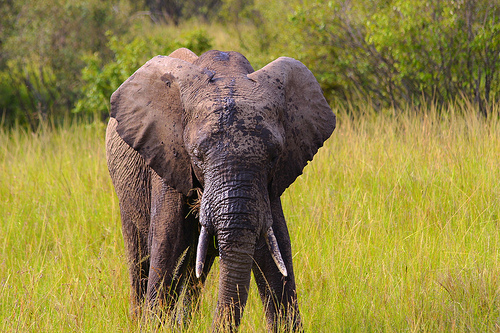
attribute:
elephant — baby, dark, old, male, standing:
[90, 32, 351, 333]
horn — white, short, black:
[257, 223, 296, 283]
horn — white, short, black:
[190, 223, 212, 280]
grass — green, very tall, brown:
[302, 171, 494, 332]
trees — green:
[5, 5, 486, 103]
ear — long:
[256, 48, 345, 200]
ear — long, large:
[101, 53, 190, 200]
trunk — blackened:
[204, 213, 266, 330]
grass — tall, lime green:
[4, 262, 492, 333]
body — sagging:
[102, 134, 152, 219]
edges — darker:
[106, 90, 168, 184]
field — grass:
[21, 126, 498, 332]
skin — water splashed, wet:
[137, 45, 307, 332]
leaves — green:
[75, 25, 214, 58]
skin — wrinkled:
[100, 44, 340, 333]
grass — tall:
[329, 146, 479, 311]